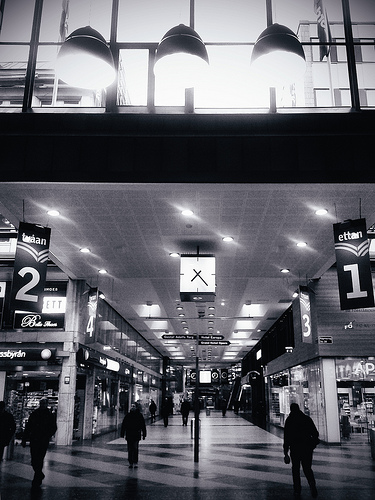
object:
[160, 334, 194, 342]
sign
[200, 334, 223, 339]
lettering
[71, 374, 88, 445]
doorway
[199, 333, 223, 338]
sign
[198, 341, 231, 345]
sign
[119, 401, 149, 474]
person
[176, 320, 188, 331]
light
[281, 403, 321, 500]
person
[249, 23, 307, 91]
light fixture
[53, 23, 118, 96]
fixture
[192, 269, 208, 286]
hand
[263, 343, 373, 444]
store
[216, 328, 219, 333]
light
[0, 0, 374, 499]
mall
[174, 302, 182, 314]
overhead light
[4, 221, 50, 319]
banners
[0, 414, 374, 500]
walkway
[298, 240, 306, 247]
light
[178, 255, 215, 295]
clock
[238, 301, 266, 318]
square lights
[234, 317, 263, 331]
square lights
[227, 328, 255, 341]
square lights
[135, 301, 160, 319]
square lights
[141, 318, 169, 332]
square lights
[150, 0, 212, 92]
light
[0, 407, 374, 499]
floor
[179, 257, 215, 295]
clock face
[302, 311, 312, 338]
number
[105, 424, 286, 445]
tile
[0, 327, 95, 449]
storefronts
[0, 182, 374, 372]
ceiling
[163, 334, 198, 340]
writing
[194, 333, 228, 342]
writing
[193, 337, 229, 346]
writing